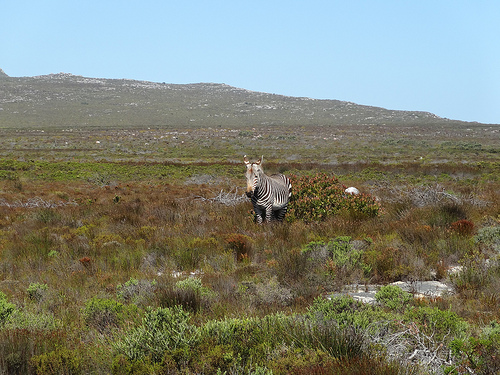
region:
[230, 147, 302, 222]
a zebra standing in a field.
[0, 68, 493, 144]
a brown mountain range.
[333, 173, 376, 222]
a zebra in a field.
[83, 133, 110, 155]
a white object in a field.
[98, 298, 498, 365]
a leafy green plant.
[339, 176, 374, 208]
a large white object.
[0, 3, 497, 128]
a light blue sky.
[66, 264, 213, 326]
a cluster of wild plant life.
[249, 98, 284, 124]
a section of white hill.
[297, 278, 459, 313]
a rock in a field.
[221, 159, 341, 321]
Large animal standing in field.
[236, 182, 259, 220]
Zebra has black nose.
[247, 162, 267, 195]
Brown mark on zebra's head.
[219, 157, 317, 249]
Zebra is black and white.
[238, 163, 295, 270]
Zebra has many stripes.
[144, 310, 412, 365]
Greenery in field near zebra.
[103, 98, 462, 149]
Hillside in distance.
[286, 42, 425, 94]
Sky is blue and clear.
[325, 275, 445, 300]
Large rock in field.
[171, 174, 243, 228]
Pile of sticks in field.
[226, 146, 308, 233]
zebra standing in the plains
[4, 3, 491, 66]
blue sky in the distance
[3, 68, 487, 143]
mountains in the background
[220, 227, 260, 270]
brown bush in the field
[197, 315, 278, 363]
green bush in the field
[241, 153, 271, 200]
face of a zebra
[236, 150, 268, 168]
ears of a zebra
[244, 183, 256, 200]
nose and mouth of a zebra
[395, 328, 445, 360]
branches in a field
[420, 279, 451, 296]
rocks in the field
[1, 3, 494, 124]
a pale blue sky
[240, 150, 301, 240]
a zebra in a field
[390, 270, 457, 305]
a rock in the ground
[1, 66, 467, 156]
a hill in the distance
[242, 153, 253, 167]
a striped zebra ear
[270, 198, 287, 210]
a white underbelly on a zebra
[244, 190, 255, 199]
a black zebra nose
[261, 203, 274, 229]
a front leg on a zebra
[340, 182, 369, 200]
a round white object peeking over a bush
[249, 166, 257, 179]
a brown spot on a zebra's forehead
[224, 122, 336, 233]
a zebra on the field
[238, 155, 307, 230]
the zebra has stripes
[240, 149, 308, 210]
a black and white zebra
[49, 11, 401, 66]
the sky is clear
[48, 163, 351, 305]
grasses on the ground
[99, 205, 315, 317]
green and brown grasses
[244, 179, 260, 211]
zebra's nose is brown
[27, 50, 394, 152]
a mountain in the distance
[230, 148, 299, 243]
the zebra is standing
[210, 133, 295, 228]
the zebra is looking